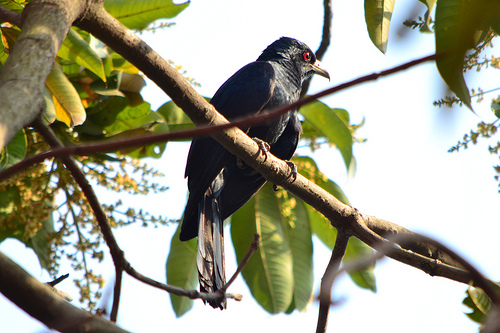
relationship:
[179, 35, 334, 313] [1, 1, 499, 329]
bird in sky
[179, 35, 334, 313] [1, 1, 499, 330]
bird sitting in tree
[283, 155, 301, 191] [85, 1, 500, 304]
claw wrapped around branch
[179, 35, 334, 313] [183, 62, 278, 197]
bird has wing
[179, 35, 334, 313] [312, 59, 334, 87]
bird has beak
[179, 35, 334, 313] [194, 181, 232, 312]
bird has tail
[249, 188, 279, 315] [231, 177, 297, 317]
vein on center of leaf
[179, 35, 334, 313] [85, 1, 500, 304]
bird sitting on branch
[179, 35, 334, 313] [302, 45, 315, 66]
bird has eye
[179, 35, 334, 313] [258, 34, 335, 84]
bird has head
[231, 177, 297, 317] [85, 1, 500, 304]
leaf on side of branch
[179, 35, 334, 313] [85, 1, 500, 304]
bird on top of branch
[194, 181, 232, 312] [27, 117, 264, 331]
tail hanging over branch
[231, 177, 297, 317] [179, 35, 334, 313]
leaf below bird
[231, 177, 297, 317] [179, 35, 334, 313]
leaf behind bird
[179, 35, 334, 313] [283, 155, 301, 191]
bird has claw